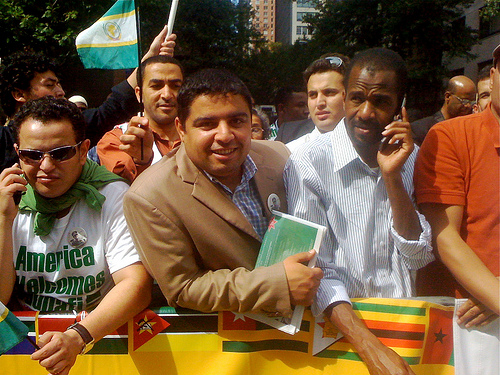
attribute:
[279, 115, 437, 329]
shirt — white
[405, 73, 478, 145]
man — bald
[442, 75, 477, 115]
head — bald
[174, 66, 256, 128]
brown hair — dark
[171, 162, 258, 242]
lapel — brown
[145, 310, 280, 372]
flag — yellow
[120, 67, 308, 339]
man — smiling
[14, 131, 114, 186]
glasses — retro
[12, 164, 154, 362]
shirt — white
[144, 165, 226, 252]
jacket — brown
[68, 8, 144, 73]
flag — green, yellow, white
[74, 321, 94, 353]
watch — brown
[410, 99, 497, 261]
shirt — orange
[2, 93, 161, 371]
man — happy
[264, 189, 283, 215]
button — small, round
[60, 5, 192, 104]
flag — large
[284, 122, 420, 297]
shirt — white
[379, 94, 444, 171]
cell phone — black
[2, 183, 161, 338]
shirt — white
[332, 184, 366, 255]
stripes — blue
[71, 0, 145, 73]
flag — yellow, white, green